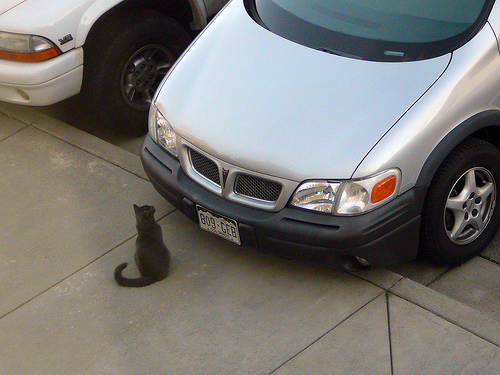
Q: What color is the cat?
A: Black.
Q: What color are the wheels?
A: Black.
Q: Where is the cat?
A: In front of the car.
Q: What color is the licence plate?
A: White.